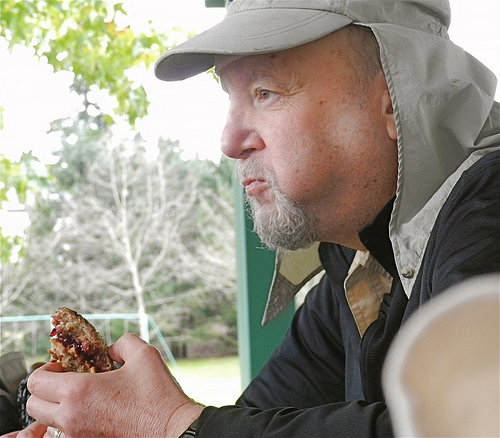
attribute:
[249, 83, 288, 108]
eye — Brown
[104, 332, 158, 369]
thumb — man.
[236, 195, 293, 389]
pillar — Green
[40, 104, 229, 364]
tree — no leaves, background.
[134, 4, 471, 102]
hat — tan flap.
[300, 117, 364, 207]
man — Light skinned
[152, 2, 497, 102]
hat — grey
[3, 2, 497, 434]
man — old , eating, wearing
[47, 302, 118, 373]
sandwich — Jelly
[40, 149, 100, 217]
tree — dead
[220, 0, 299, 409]
window bar — green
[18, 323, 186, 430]
hand — man.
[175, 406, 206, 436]
watch — man.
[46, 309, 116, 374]
sandwich — peanut butter, jelly 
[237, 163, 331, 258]
beard — gray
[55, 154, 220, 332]
tree — healthy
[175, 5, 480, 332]
tan hat — tan.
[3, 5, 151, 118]
leaves — background.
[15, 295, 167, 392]
sandwich — half-eaten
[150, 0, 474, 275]
hat — grey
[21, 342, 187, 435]
hand — holding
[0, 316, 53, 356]
fence — background.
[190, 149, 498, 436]
jacket — black, grey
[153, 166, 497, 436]
jacket — black 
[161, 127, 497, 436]
hoodie — black 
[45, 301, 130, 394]
sandwich — peanut butter, jelly